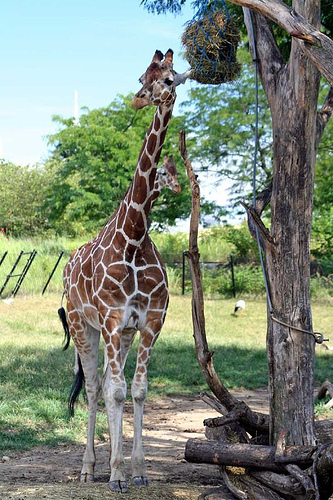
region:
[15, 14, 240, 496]
a giraffe in a zoo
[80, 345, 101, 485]
the leg of a giraffe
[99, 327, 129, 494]
the leg of a giraffe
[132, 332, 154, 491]
the leg of a giraffe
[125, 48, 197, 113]
the head of a giraffe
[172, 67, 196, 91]
the ear of a giraffe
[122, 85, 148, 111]
the nose of a giraffe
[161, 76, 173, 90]
the eye of a giraffe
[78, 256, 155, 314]
the spots of a giraffe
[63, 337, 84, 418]
the tail of a giraffe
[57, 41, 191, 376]
A giraffe is standing next to the tree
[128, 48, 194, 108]
The giraffe has two antlers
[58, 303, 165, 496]
The giraffe has four legs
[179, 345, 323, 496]
Logs are piled around the tree trunk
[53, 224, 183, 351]
The torso of the giraffe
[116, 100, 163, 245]
The neck of the giraffe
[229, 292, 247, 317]
A white bird is in the distance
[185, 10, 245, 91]
A nest hangs from the tree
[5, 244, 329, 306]
A black wired fence is in the background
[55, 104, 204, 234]
The tree has green leaves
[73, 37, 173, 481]
giraffe standing in the zoo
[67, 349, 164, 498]
leg of the giraffe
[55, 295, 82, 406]
tail of the giraffe with fringes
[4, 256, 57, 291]
steel fencing near the giraffe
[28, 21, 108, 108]
blue color sky with clouds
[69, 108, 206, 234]
tree with branches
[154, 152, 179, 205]
giraffe behind the big giraffe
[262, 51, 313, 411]
a big tree near the giraffe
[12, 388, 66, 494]
dirt with grass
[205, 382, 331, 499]
pieces of chopped wooden pieces near the tree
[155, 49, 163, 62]
The left horn on the top of the giraffe's head.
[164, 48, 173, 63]
The right horn on the giraffe's head.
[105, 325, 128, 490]
The left front leg of the giraffe.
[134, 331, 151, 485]
The front right leg of the giraffe.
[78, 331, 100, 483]
The back left leg of the giraffe.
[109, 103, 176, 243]
The neck of the giraffe.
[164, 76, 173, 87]
The right eye of the giraffe.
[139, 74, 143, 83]
The left eye of the giraffe.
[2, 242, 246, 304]
The black gate behind the giraffe.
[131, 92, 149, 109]
The nose and mouth area of the giraffe.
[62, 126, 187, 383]
the giraffe is brown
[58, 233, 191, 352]
the giraffe is brown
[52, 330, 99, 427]
the tail is black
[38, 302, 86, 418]
the tail is black